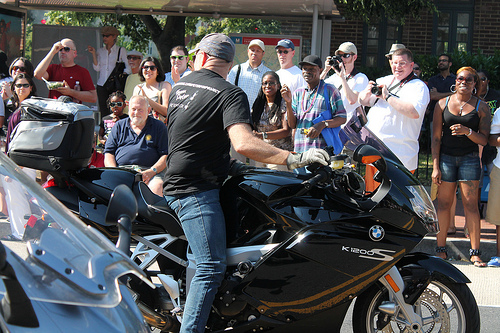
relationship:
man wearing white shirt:
[359, 48, 431, 181] [364, 74, 429, 171]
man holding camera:
[318, 39, 375, 136] [326, 51, 341, 67]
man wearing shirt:
[37, 29, 100, 133] [47, 61, 95, 101]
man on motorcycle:
[148, 17, 337, 332] [34, 121, 498, 318]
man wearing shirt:
[123, 14, 294, 331] [164, 68, 252, 195]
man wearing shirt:
[37, 29, 97, 112] [49, 63, 86, 102]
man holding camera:
[359, 48, 431, 181] [368, 81, 390, 97]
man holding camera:
[318, 39, 375, 136] [331, 55, 345, 72]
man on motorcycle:
[148, 17, 337, 332] [0, 116, 485, 331]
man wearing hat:
[148, 17, 337, 332] [183, 32, 241, 63]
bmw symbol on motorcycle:
[367, 223, 387, 242] [0, 93, 481, 331]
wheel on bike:
[354, 265, 478, 332] [89, 116, 476, 331]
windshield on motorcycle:
[310, 67, 440, 232] [0, 93, 481, 331]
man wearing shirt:
[37, 29, 100, 133] [24, 27, 96, 117]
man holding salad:
[37, 29, 100, 133] [39, 76, 67, 92]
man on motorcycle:
[148, 17, 337, 332] [0, 93, 481, 331]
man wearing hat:
[318, 39, 369, 120] [331, 40, 358, 57]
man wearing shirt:
[37, 29, 100, 133] [46, 63, 95, 95]